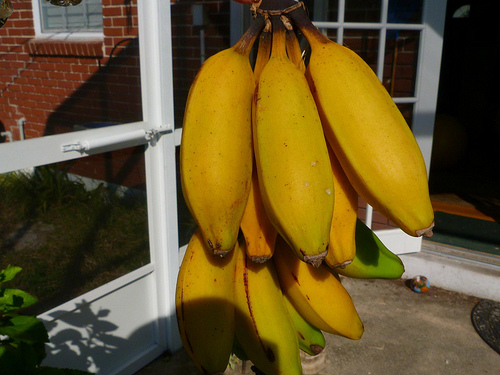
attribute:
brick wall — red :
[0, 3, 417, 208]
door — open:
[298, 7, 440, 260]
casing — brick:
[3, 1, 139, 134]